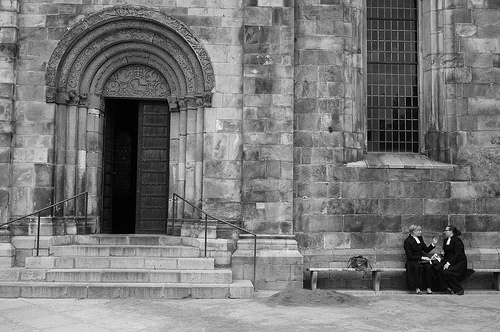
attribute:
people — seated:
[400, 216, 472, 299]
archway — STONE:
[46, 5, 216, 108]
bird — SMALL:
[337, 234, 381, 281]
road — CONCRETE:
[5, 298, 499, 328]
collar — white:
[411, 235, 428, 242]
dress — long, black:
[408, 240, 425, 282]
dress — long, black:
[446, 241, 462, 287]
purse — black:
[343, 251, 375, 274]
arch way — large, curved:
[42, 11, 224, 114]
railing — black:
[165, 189, 265, 291]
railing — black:
[3, 187, 84, 263]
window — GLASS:
[362, 0, 425, 160]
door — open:
[135, 101, 165, 231]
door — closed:
[132, 112, 192, 239]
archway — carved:
[83, 12, 208, 111]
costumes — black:
[402, 237, 474, 294]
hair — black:
[446, 223, 466, 240]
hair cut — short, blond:
[408, 221, 420, 231]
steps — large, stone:
[1, 232, 256, 302]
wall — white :
[205, 3, 379, 241]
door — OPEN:
[80, 54, 188, 264]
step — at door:
[97, 226, 168, 244]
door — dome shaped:
[94, 59, 173, 234]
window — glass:
[360, 6, 430, 159]